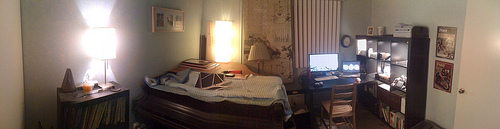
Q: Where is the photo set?
A: Apartment.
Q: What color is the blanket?
A: White.